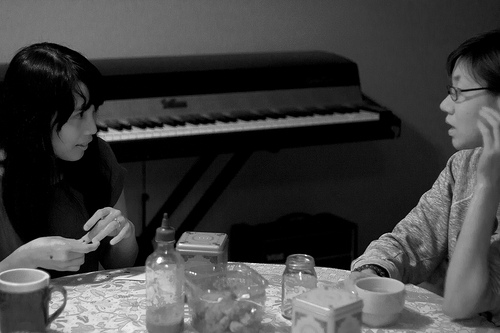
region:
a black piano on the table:
[131, 44, 337, 173]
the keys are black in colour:
[152, 105, 382, 120]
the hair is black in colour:
[7, 15, 129, 202]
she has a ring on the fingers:
[8, 177, 148, 285]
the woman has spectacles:
[399, 45, 499, 317]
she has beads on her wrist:
[339, 226, 400, 318]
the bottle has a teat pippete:
[136, 203, 216, 332]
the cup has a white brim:
[0, 248, 82, 332]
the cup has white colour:
[344, 250, 399, 332]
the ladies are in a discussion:
[2, 3, 496, 286]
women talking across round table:
[1, 22, 494, 328]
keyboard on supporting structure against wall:
[90, 50, 390, 265]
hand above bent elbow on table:
[435, 40, 495, 320]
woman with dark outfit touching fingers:
[2, 35, 132, 270]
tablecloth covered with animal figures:
[46, 256, 481, 326]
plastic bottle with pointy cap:
[145, 205, 181, 326]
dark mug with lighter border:
[0, 260, 65, 326]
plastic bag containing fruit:
[180, 256, 265, 326]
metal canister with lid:
[287, 275, 362, 330]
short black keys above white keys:
[96, 101, 379, 141]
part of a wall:
[383, 179, 390, 187]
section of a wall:
[311, 219, 318, 234]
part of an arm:
[449, 290, 459, 298]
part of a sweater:
[421, 240, 429, 251]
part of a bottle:
[164, 279, 166, 288]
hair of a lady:
[6, 105, 36, 145]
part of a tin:
[296, 272, 301, 284]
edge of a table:
[131, 276, 136, 280]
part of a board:
[258, 145, 268, 154]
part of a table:
[413, 314, 425, 321]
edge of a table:
[117, 309, 132, 321]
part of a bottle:
[158, 292, 166, 309]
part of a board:
[232, 113, 246, 131]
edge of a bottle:
[144, 291, 154, 306]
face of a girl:
[72, 137, 83, 144]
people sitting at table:
[9, 38, 490, 284]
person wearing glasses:
[429, 30, 497, 157]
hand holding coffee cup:
[327, 228, 454, 331]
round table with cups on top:
[6, 210, 496, 330]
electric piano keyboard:
[6, 45, 401, 194]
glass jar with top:
[134, 210, 185, 332]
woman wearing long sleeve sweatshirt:
[346, 33, 491, 330]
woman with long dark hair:
[3, 35, 121, 263]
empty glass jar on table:
[270, 232, 350, 331]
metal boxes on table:
[171, 210, 374, 329]